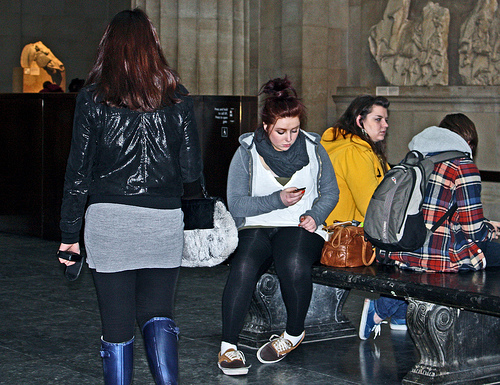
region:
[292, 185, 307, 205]
Phone one of the girls is holding.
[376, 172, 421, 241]
Bookbag one of the girls is wearing.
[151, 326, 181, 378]
Knee high boots one of the girls is wearing.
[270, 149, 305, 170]
Scarf one of the girls is wearing.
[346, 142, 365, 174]
Yellow jacket one of the girls is wearing.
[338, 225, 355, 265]
Purse that belongs to one of the girls.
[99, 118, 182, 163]
Black jacket one of the girls is wearing.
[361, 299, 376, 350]
Blue sneakers one of the girls is wearing.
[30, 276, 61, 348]
Gray marble floor in the building.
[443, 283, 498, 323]
Bench 3 of the girls are sitting on.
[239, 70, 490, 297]
Three people sharing a bench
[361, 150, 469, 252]
a grey backpack on a persons back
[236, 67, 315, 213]
a young woman looking at her phone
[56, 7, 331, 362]
two girls wearing black spandex pants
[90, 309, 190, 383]
a pair of blue shiny boots on a girl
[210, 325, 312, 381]
two shades of brown colored shoes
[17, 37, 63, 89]
a wooden sculpture of a horses head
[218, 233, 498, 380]
a black and grey granite bench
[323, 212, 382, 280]
a brown purse sitting on the bench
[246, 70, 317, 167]
a girl with her brown hair up in a bun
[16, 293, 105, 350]
floor is black color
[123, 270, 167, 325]
pant is black color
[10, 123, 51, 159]
desk is brown color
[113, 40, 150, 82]
hair is brown color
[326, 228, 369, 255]
hand bag is brown color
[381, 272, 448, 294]
bench is black color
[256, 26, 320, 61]
wall is brown color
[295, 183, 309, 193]
mobile is black color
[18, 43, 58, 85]
statue is brown color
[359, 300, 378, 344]
shoe is blue color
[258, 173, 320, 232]
the woman is looking at her phone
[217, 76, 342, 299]
the woman is holding a phone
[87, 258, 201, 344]
the leggings are black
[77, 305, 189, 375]
the boots is violet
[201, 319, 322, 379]
the shoes is brown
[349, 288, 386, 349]
the sneakers is blue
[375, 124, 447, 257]
the bag is gray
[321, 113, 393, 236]
the jacket is yellow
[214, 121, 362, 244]
the shirt is white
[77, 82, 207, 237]
the jacket is black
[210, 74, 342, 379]
Girl looking at phone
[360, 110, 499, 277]
Guy wearing a backpack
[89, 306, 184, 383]
Girl wearing blue boots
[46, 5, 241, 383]
Girl walking inside museum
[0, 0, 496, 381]
People in museum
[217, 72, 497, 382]
Three people sitting on bench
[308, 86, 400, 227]
Girl wearing yellow sweater in museum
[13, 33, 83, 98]
Horse statue in museum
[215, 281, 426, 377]
Girls wearing shoes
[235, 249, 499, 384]
Concrete bench in museum